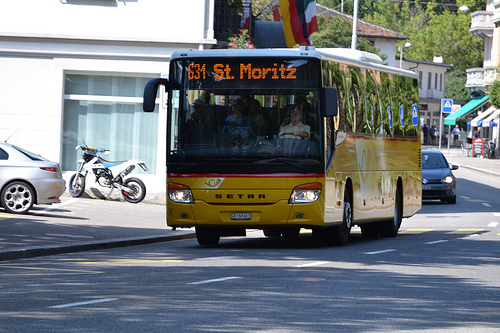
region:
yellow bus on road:
[142, 45, 420, 244]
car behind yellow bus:
[415, 147, 459, 205]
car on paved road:
[415, 149, 461, 205]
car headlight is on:
[443, 175, 452, 183]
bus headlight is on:
[168, 188, 193, 204]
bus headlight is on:
[290, 186, 321, 203]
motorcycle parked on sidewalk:
[68, 143, 144, 200]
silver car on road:
[0, 132, 63, 214]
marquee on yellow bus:
[170, 56, 320, 86]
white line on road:
[49, 296, 121, 308]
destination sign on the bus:
[183, 63, 297, 85]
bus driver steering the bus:
[279, 108, 317, 153]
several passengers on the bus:
[184, 91, 261, 138]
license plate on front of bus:
[230, 210, 257, 220]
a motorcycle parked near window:
[70, 127, 143, 200]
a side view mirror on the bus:
[320, 80, 338, 117]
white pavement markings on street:
[41, 237, 471, 308]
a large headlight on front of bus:
[293, 183, 319, 200]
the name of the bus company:
[211, 187, 266, 200]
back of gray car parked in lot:
[0, 141, 61, 213]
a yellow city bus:
[132, 45, 432, 241]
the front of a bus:
[170, 50, 325, 222]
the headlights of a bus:
[169, 184, 322, 206]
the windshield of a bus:
[171, 89, 323, 164]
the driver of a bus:
[272, 106, 310, 143]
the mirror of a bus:
[133, 75, 158, 112]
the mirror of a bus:
[316, 80, 340, 117]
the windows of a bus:
[321, 63, 419, 140]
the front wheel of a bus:
[328, 177, 358, 244]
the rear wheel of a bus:
[384, 173, 406, 235]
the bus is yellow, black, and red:
[96, 16, 454, 261]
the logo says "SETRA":
[204, 190, 281, 205]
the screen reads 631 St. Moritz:
[175, 57, 328, 87]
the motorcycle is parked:
[66, 132, 154, 209]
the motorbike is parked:
[61, 127, 163, 217]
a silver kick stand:
[98, 182, 120, 206]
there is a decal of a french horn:
[190, 172, 242, 194]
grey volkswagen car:
[409, 135, 474, 205]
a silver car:
[0, 133, 84, 230]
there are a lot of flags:
[230, 0, 335, 57]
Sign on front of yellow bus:
[176, 56, 317, 86]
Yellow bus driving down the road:
[142, 48, 423, 247]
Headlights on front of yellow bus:
[168, 183, 318, 205]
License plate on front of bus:
[228, 211, 251, 219]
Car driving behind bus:
[422, 149, 458, 204]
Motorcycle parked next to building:
[68, 143, 146, 202]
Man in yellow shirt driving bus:
[276, 104, 312, 139]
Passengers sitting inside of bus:
[189, 84, 276, 144]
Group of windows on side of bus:
[328, 60, 422, 139]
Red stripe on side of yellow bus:
[342, 133, 418, 143]